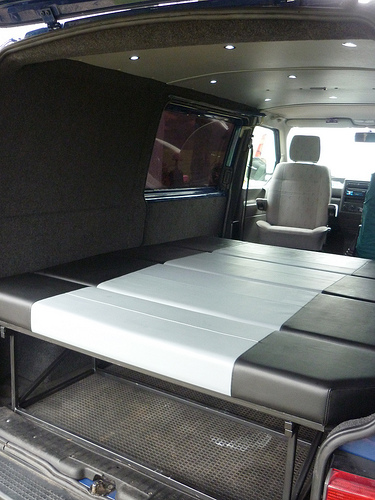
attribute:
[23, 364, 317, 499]
interior — black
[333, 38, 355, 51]
light — small, lit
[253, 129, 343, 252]
seat — white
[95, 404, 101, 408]
bump — small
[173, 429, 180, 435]
bump — small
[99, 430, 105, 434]
bump — small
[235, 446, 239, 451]
bump — small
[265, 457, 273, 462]
bump — small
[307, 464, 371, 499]
light — red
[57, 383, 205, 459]
bumps — small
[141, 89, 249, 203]
window — dark, shaded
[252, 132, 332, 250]
seat — white, cushion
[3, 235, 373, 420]
cushions — white, black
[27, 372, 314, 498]
bumps — small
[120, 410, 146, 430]
bumps — small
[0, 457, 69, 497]
bumps — small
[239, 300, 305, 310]
bumps — small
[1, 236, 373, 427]
seating — down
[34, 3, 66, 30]
latch — black, metallic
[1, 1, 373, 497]
vehicle — black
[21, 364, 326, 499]
bumps — small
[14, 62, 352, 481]
interior — black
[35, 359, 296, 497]
bumps — small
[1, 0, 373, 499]
interior — black